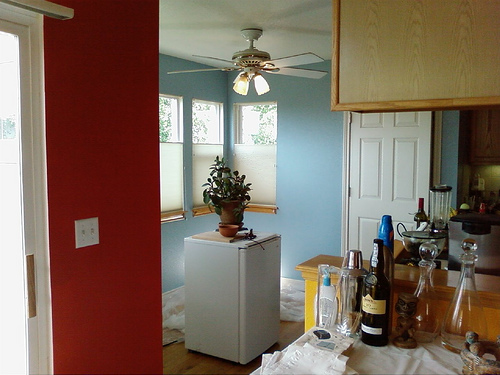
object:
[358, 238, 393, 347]
bottle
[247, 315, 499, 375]
table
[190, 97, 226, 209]
window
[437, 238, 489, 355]
glass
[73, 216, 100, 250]
switch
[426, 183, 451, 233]
blender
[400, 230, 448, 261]
bowl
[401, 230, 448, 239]
lid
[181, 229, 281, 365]
fridge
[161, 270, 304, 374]
floor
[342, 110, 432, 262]
door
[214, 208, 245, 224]
planter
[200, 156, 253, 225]
plant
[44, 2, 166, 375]
wall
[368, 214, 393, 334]
bottle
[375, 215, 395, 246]
lid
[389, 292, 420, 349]
knick knack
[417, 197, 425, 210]
top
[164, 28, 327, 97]
fan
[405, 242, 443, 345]
bottle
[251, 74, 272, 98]
lights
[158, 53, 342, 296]
wall